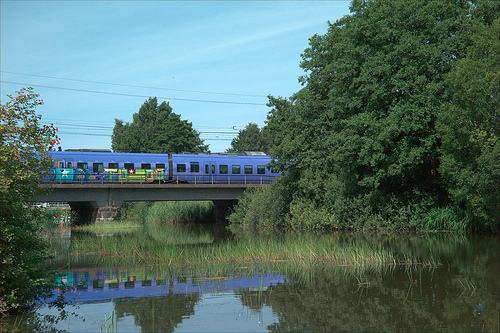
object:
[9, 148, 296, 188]
train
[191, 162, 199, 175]
window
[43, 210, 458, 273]
grass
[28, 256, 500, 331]
reflection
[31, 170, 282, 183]
guard rail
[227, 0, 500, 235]
tree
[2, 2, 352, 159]
sky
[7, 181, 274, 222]
bridge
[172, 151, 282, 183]
train car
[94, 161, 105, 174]
window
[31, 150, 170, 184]
train car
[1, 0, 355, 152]
cloud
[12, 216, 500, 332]
water